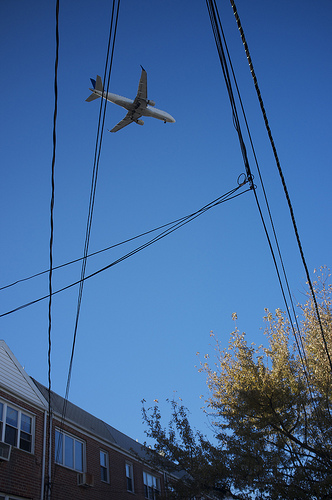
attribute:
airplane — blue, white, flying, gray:
[85, 67, 174, 136]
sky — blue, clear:
[2, 0, 331, 464]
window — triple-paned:
[57, 425, 85, 469]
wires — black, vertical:
[200, 2, 330, 464]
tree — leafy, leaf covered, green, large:
[120, 284, 323, 499]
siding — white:
[4, 346, 52, 406]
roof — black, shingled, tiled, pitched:
[35, 368, 201, 495]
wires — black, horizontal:
[6, 154, 254, 338]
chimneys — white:
[132, 434, 172, 459]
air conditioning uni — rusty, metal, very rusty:
[76, 464, 96, 493]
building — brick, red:
[3, 343, 222, 499]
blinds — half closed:
[2, 404, 36, 430]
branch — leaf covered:
[210, 313, 331, 452]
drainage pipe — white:
[37, 408, 60, 500]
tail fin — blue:
[91, 76, 101, 94]